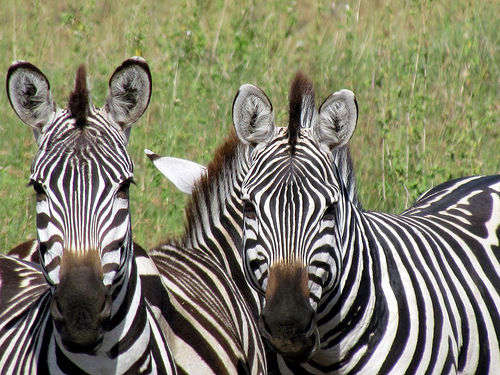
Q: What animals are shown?
A: Zebras.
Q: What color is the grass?
A: Green.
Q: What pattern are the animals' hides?
A: Striped.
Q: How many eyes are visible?
A: Four.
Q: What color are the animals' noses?
A: Brown.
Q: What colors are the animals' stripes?
A: Black and white.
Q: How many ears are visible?
A: Five.